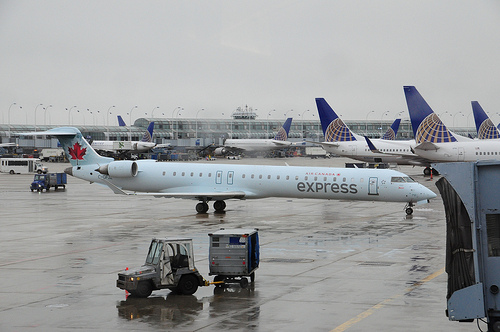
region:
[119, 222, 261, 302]
a luggage truck on the tarmac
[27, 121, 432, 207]
a white jet airplane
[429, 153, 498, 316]
an unused jetway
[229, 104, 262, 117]
a control tower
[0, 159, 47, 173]
a white bus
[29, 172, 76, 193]
a blue truck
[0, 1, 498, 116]
grey gloomy skies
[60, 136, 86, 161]
a red oak leaf on the tail of a plane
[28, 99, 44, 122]
a tall lightpost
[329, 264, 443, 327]
a long yellow stripe painted on the tarmac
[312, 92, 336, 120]
the plane's tail is blue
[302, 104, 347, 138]
the plane's tail is blue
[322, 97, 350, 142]
the plane's tail is blue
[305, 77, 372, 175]
the plane's tail is blue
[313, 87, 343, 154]
the plane's tail is blue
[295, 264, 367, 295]
the road is wet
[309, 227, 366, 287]
the road is wet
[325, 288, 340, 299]
the road is wet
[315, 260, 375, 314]
the road is wet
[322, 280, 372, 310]
the road is wet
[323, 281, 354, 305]
the road is wet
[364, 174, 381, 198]
the door of a plane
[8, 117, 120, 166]
the tail of a plane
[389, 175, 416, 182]
the windshield of a plane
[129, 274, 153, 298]
a wheel on the car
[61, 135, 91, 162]
a red maple leaf on the plane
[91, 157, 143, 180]
the engine of a plane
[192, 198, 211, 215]
a black wheel on the plane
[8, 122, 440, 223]
a white plane on the tarmac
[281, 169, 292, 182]
a window on the plane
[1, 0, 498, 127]
a gray sky overhead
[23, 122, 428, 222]
an airplane sitting on a runway on a rainy day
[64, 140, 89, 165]
a maple leaf emblem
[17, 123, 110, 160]
the tail wing of a plane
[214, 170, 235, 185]
doors on a plane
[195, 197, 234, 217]
wheels on a plane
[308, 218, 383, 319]
a wet runway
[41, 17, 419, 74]
a hazy sky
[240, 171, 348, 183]
the windows on a plane